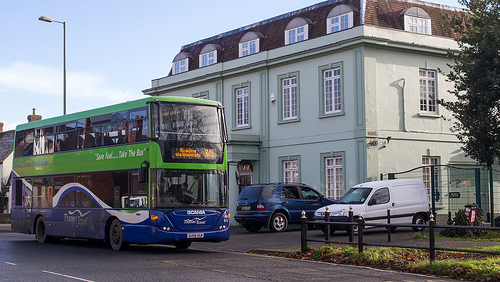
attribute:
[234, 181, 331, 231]
vehicle — parked, blue, small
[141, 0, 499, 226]
building — green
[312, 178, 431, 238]
van — parked, white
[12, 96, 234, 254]
bus — double-decker, green, blue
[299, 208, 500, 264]
fence — black, wooden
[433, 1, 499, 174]
tree — green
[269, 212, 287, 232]
tire — black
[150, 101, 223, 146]
window — black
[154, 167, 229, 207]
window — black